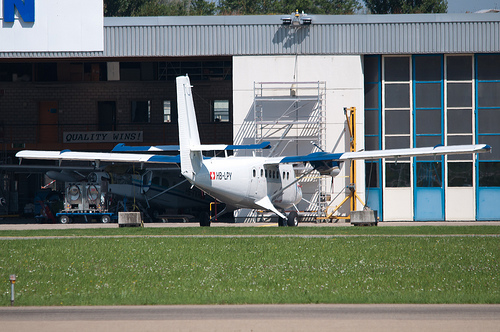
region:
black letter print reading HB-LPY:
[214, 169, 234, 179]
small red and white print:
[208, 170, 218, 180]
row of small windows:
[249, 168, 291, 180]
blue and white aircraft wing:
[261, 140, 490, 162]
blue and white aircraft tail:
[111, 73, 273, 181]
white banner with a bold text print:
[60, 127, 142, 140]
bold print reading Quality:
[60, 127, 110, 138]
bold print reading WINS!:
[107, 130, 139, 140]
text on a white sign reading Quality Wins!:
[61, 128, 146, 142]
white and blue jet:
[13, 73, 495, 228]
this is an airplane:
[8, 72, 498, 239]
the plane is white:
[9, 83, 498, 253]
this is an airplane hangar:
[2, 23, 497, 229]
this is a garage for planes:
[0, 12, 499, 242]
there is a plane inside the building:
[25, 136, 186, 217]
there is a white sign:
[48, 122, 165, 147]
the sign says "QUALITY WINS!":
[47, 108, 165, 152]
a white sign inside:
[50, 117, 174, 154]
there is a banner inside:
[45, 119, 166, 150]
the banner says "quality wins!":
[49, 113, 170, 157]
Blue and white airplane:
[14, 78, 493, 228]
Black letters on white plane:
[214, 169, 234, 180]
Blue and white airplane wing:
[280, 144, 495, 171]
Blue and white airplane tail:
[106, 69, 274, 155]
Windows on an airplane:
[248, 163, 295, 178]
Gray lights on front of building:
[276, 10, 320, 35]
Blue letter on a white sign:
[3, 3, 45, 31]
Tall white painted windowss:
[381, 58, 413, 140]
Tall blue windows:
[410, 57, 445, 141]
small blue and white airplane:
[13, 73, 490, 227]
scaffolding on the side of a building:
[252, 78, 324, 219]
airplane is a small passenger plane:
[15, 74, 492, 226]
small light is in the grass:
[7, 270, 16, 305]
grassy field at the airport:
[3, 223, 498, 304]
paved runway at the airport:
[1, 301, 497, 330]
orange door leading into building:
[35, 95, 62, 144]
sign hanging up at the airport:
[61, 128, 144, 143]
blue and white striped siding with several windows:
[364, 54, 499, 221]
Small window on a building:
[383, 54, 405, 81]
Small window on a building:
[381, 81, 414, 113]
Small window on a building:
[381, 107, 413, 136]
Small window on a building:
[412, 158, 442, 193]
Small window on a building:
[447, 157, 478, 187]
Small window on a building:
[478, 158, 498, 179]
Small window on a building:
[475, 103, 498, 128]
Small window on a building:
[417, 108, 439, 133]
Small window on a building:
[446, 82, 476, 112]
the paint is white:
[181, 154, 205, 174]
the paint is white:
[235, 159, 250, 191]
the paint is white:
[345, 141, 486, 158]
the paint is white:
[447, 189, 472, 219]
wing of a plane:
[272, 144, 487, 165]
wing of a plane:
[17, 147, 176, 161]